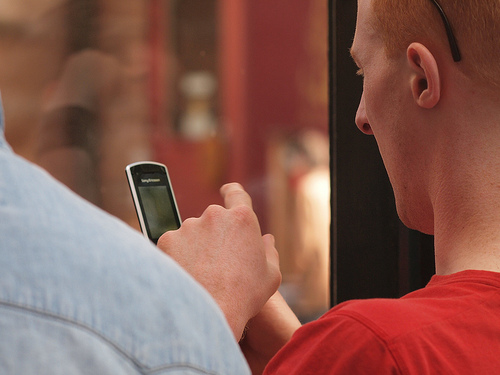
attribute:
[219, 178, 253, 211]
finger — extended 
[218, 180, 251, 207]
finger — extended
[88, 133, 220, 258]
cell phone — silver-and-black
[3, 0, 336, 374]
window — large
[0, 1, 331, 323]
window — large 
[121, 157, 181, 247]
phone — black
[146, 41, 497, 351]
people — close-up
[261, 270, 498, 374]
shirt — red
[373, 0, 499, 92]
hair — orange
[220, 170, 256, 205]
finger — outreaching